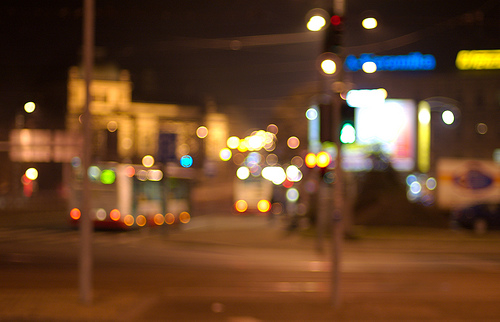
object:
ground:
[1, 228, 500, 322]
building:
[327, 2, 498, 228]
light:
[22, 98, 37, 115]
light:
[101, 170, 117, 184]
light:
[250, 123, 285, 149]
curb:
[372, 234, 490, 253]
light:
[302, 14, 327, 33]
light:
[317, 59, 336, 74]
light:
[360, 60, 377, 74]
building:
[8, 47, 285, 230]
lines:
[131, 25, 306, 75]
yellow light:
[315, 152, 330, 170]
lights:
[233, 200, 279, 215]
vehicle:
[227, 182, 285, 214]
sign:
[343, 42, 446, 76]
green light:
[342, 105, 359, 149]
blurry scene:
[2, 7, 500, 322]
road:
[1, 215, 499, 319]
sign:
[333, 100, 358, 145]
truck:
[432, 156, 499, 233]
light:
[136, 215, 149, 228]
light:
[110, 210, 189, 224]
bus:
[72, 159, 199, 231]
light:
[308, 153, 334, 166]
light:
[317, 149, 329, 166]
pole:
[77, 0, 90, 303]